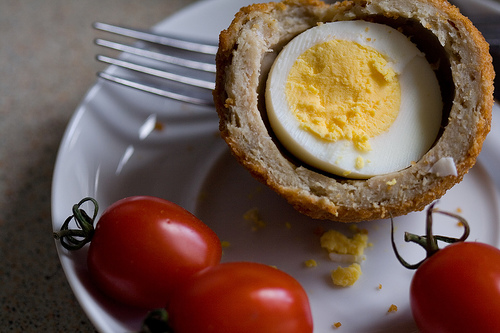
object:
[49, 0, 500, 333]
plate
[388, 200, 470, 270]
stem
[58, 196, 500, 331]
tomato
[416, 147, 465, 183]
ground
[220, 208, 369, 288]
crumbs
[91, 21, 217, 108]
fork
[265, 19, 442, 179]
egg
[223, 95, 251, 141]
wall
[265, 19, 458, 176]
egg white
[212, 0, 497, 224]
bread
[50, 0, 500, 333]
breakfast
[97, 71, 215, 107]
tines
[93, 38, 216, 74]
tines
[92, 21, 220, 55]
tines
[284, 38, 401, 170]
egg yolk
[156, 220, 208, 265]
light